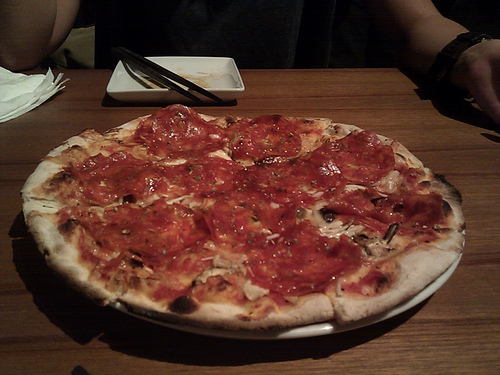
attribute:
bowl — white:
[110, 53, 249, 105]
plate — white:
[14, 95, 480, 350]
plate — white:
[119, 227, 471, 373]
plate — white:
[102, 50, 249, 97]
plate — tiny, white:
[82, 47, 278, 106]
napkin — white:
[16, 61, 97, 119]